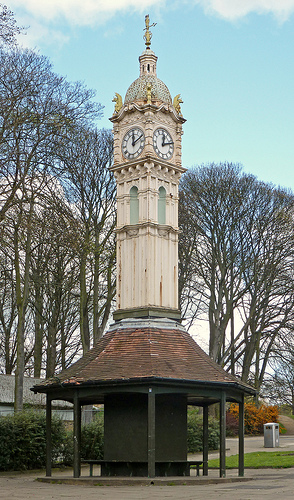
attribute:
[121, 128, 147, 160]
clock — black, white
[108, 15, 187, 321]
tower — tall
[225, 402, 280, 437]
bush — orange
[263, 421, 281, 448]
trash can — silver, siver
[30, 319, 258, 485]
gazebo — old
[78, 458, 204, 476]
bench — wooden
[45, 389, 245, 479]
posts — wooden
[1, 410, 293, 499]
sidewalk — empty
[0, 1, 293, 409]
trees — bare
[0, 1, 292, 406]
clouds — white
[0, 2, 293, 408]
sky — blue